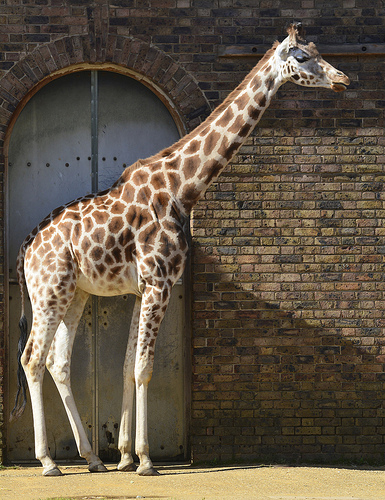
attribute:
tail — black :
[15, 236, 28, 420]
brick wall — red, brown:
[1, 0, 384, 472]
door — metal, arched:
[94, 68, 196, 467]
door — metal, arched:
[4, 61, 99, 465]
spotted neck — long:
[166, 58, 282, 217]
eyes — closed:
[291, 39, 310, 70]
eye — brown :
[293, 53, 310, 61]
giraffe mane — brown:
[118, 42, 277, 171]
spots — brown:
[14, 54, 335, 382]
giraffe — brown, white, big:
[9, 22, 350, 476]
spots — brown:
[37, 222, 172, 261]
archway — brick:
[16, 42, 207, 139]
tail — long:
[7, 241, 30, 424]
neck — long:
[138, 51, 287, 213]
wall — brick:
[4, 5, 384, 464]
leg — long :
[17, 256, 75, 473]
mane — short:
[119, 40, 279, 180]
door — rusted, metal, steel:
[0, 65, 194, 469]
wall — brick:
[271, 144, 328, 243]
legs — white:
[19, 363, 174, 480]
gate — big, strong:
[0, 65, 189, 466]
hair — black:
[14, 310, 32, 412]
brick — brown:
[254, 230, 363, 416]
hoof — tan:
[83, 462, 108, 471]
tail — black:
[11, 254, 33, 422]